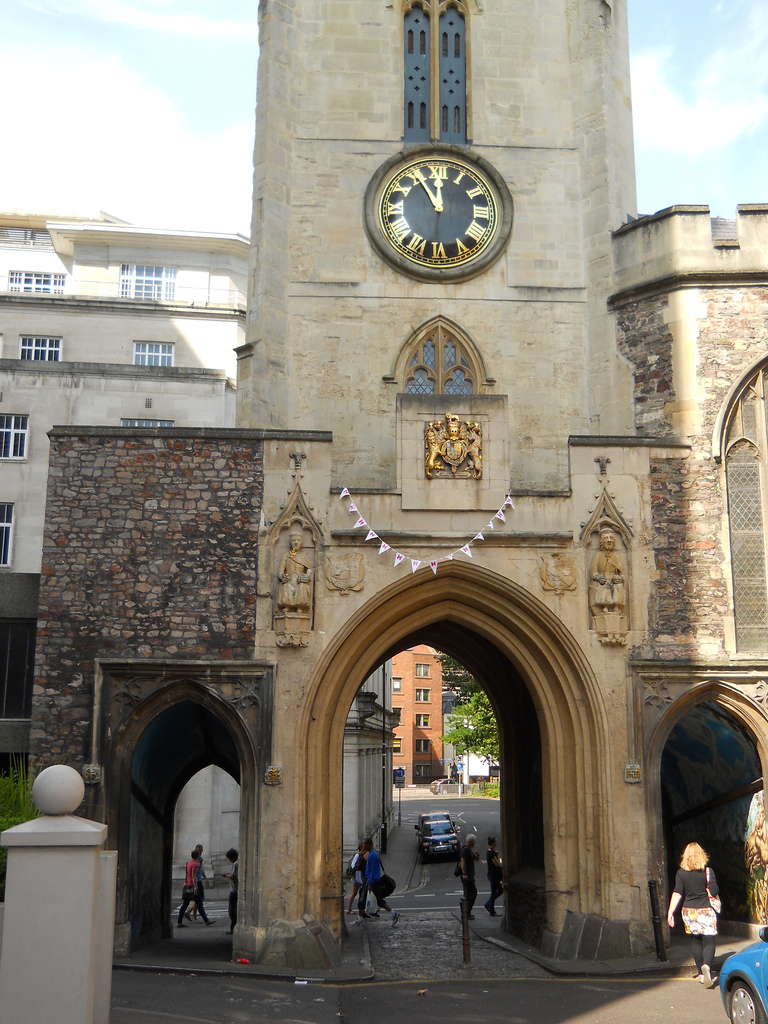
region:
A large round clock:
[349, 142, 532, 280]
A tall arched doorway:
[307, 564, 618, 968]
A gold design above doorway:
[415, 402, 496, 494]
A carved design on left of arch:
[262, 453, 326, 679]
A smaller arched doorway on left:
[103, 666, 271, 981]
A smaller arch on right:
[643, 679, 765, 948]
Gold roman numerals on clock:
[364, 138, 526, 292]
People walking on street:
[346, 818, 501, 927]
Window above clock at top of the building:
[393, 4, 479, 140]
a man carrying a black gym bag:
[348, 834, 410, 929]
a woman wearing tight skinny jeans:
[167, 850, 222, 938]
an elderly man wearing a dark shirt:
[453, 827, 485, 924]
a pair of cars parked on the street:
[414, 810, 473, 864]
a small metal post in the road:
[453, 889, 481, 972]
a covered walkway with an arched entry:
[113, 682, 264, 961]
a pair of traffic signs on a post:
[388, 758, 411, 792]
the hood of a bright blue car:
[715, 936, 766, 1007]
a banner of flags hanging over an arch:
[323, 479, 518, 578]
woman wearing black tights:
[687, 931, 717, 963]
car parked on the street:
[419, 815, 457, 853]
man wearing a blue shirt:
[358, 852, 383, 883]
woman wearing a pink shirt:
[179, 858, 202, 885]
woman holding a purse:
[700, 863, 723, 916]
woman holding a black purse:
[373, 869, 398, 896]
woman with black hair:
[218, 843, 237, 867]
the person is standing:
[458, 838, 483, 926]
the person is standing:
[357, 848, 395, 917]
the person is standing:
[224, 851, 242, 917]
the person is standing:
[178, 840, 215, 926]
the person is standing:
[663, 826, 729, 963]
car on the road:
[413, 815, 465, 864]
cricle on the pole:
[8, 764, 88, 813]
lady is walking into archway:
[665, 839, 723, 986]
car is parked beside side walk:
[416, 817, 465, 863]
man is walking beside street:
[450, 829, 480, 916]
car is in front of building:
[718, 919, 765, 1019]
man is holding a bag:
[359, 835, 401, 927]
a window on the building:
[142, 330, 159, 353]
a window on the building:
[419, 705, 438, 730]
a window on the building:
[411, 681, 435, 708]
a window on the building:
[418, 662, 450, 682]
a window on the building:
[408, 738, 432, 773]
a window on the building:
[10, 403, 44, 447]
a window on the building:
[106, 342, 177, 382]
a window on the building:
[13, 329, 53, 376]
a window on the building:
[87, 263, 185, 316]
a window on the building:
[385, 339, 533, 422]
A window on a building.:
[120, 418, 172, 431]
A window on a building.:
[132, 337, 184, 375]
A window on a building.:
[125, 262, 179, 301]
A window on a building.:
[22, 333, 63, 356]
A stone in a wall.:
[111, 518, 130, 526]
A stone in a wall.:
[161, 499, 180, 508]